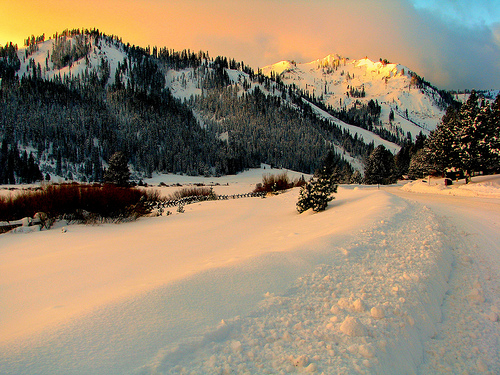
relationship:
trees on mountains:
[1, 40, 499, 179] [0, 23, 498, 189]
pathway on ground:
[374, 176, 500, 372] [9, 162, 498, 374]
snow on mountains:
[52, 43, 428, 164] [0, 23, 498, 189]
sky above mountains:
[0, 1, 499, 97] [0, 23, 498, 189]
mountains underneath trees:
[0, 23, 498, 189] [1, 40, 499, 179]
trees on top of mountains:
[1, 40, 499, 179] [0, 23, 498, 189]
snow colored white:
[52, 43, 428, 164] [370, 75, 398, 97]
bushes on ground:
[5, 178, 312, 220] [9, 162, 498, 374]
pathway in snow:
[374, 176, 500, 372] [52, 43, 428, 164]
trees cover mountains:
[1, 40, 499, 179] [0, 23, 498, 189]